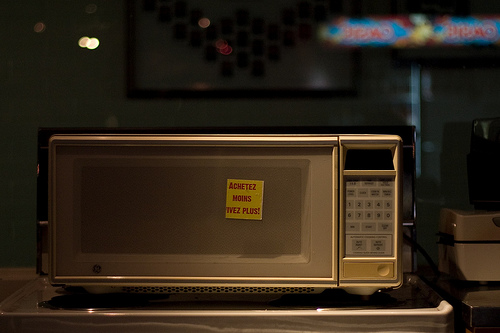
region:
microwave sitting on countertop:
[22, 120, 414, 292]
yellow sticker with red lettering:
[218, 176, 271, 221]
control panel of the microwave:
[339, 175, 395, 257]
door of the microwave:
[51, 139, 332, 283]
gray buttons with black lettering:
[342, 175, 393, 257]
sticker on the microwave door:
[217, 164, 266, 226]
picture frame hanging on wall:
[116, 40, 372, 107]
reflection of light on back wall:
[65, 36, 102, 53]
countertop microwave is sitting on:
[10, 270, 462, 330]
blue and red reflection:
[319, 6, 499, 52]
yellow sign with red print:
[224, 176, 265, 221]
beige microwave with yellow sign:
[50, 131, 402, 289]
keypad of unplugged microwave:
[341, 174, 394, 259]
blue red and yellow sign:
[315, 10, 498, 51]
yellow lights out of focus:
[76, 30, 100, 52]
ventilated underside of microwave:
[59, 280, 351, 301]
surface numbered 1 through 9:
[343, 196, 395, 223]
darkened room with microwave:
[10, 10, 487, 330]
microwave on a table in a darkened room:
[9, 77, 461, 330]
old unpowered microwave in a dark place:
[20, 33, 456, 330]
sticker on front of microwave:
[223, 177, 265, 225]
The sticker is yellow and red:
[226, 178, 266, 223]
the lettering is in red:
[221, 178, 266, 219]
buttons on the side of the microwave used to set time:
[345, 178, 392, 256]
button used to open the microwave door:
[343, 263, 394, 282]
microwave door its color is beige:
[51, 145, 341, 284]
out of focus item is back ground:
[326, 20, 498, 42]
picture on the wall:
[121, 6, 358, 101]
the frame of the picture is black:
[118, 2, 135, 94]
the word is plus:
[241, 208, 258, 215]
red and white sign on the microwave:
[225, 177, 270, 223]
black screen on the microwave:
[334, 139, 401, 176]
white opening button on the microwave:
[340, 258, 397, 280]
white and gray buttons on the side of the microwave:
[340, 178, 399, 267]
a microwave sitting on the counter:
[36, 120, 413, 297]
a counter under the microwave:
[1, 275, 460, 332]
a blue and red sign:
[322, 12, 497, 47]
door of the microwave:
[47, 140, 339, 278]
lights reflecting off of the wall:
[26, 9, 121, 59]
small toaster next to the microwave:
[428, 197, 498, 299]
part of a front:
[256, 199, 308, 245]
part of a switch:
[347, 253, 378, 284]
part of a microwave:
[223, 236, 268, 273]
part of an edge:
[344, 266, 401, 297]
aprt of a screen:
[252, 226, 301, 276]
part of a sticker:
[334, 221, 373, 281]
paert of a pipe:
[406, 241, 433, 287]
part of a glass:
[249, 184, 285, 249]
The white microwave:
[33, 109, 414, 298]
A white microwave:
[35, 119, 422, 302]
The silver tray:
[6, 263, 452, 325]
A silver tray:
[5, 273, 492, 330]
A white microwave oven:
[36, 127, 414, 307]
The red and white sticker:
[216, 171, 282, 234]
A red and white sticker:
[216, 167, 286, 231]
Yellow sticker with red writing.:
[223, 179, 265, 222]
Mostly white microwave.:
[36, 124, 417, 299]